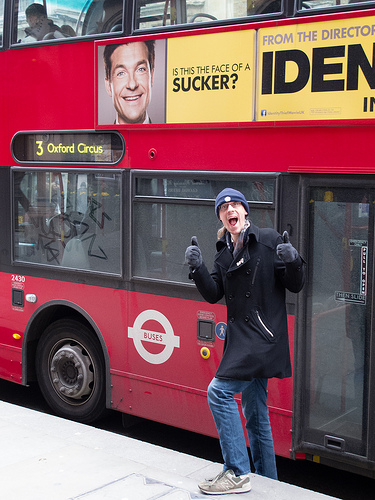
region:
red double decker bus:
[3, 3, 367, 463]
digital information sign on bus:
[5, 123, 130, 174]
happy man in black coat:
[170, 183, 312, 498]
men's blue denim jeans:
[201, 351, 287, 499]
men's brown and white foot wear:
[189, 461, 260, 495]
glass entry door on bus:
[288, 170, 373, 470]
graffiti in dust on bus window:
[6, 166, 130, 279]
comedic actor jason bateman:
[92, 35, 164, 127]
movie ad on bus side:
[84, 4, 373, 144]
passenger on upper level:
[10, 3, 79, 48]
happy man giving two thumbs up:
[182, 184, 307, 495]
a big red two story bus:
[2, 2, 372, 479]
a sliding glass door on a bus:
[297, 181, 372, 466]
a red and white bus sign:
[126, 307, 181, 365]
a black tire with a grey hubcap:
[32, 316, 108, 424]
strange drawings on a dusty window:
[12, 190, 112, 266]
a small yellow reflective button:
[11, 332, 21, 340]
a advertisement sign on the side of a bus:
[94, 14, 373, 125]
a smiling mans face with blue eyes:
[101, 38, 156, 128]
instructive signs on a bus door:
[333, 239, 374, 308]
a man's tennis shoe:
[198, 467, 253, 494]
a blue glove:
[275, 232, 294, 260]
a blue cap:
[209, 187, 251, 210]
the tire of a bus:
[38, 317, 101, 419]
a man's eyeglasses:
[216, 201, 241, 212]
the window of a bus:
[13, 168, 125, 274]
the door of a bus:
[302, 179, 370, 447]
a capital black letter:
[310, 43, 346, 93]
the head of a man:
[212, 187, 250, 235]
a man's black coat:
[185, 223, 307, 379]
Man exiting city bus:
[1, 1, 373, 496]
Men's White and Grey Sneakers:
[195, 467, 258, 494]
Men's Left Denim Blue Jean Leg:
[207, 376, 247, 472]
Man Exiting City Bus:
[184, 193, 299, 496]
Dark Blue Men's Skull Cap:
[209, 184, 249, 207]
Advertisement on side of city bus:
[92, 35, 374, 125]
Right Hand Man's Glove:
[180, 232, 205, 272]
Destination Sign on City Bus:
[9, 129, 126, 165]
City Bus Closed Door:
[299, 173, 371, 473]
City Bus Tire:
[32, 321, 109, 415]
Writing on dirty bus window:
[32, 192, 111, 261]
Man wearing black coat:
[195, 187, 302, 493]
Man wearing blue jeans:
[189, 185, 295, 498]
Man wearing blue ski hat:
[199, 186, 296, 496]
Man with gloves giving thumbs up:
[177, 181, 302, 281]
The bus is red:
[110, 302, 201, 405]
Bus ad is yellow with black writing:
[97, 18, 372, 124]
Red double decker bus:
[4, 1, 163, 440]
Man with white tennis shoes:
[195, 180, 298, 498]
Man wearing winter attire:
[198, 188, 299, 493]